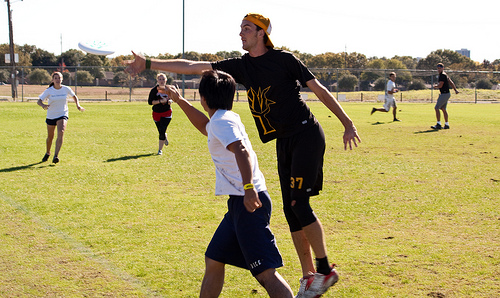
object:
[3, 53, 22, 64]
transformer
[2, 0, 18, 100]
utility pole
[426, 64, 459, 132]
person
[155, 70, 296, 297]
person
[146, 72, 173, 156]
person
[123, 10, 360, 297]
man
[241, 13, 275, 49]
hat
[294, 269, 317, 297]
shoe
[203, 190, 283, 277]
shorts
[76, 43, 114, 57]
frisbee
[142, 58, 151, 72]
ankle brace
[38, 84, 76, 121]
shirt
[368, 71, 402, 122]
man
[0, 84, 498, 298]
grass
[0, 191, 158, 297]
line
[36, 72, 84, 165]
girl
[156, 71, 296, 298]
boy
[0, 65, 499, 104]
fence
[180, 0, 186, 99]
pole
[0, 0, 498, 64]
sky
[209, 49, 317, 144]
shirt